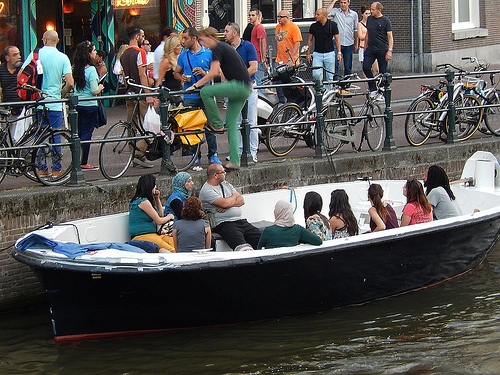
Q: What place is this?
A: It is a walkway.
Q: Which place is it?
A: It is a walkway.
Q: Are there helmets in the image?
A: No, there are no helmets.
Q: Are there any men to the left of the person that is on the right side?
A: Yes, there is a man to the left of the person.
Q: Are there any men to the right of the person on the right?
A: No, the man is to the left of the person.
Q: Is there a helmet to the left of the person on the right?
A: No, there is a man to the left of the person.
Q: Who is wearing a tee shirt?
A: The man is wearing a tee shirt.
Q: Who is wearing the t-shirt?
A: The man is wearing a tee shirt.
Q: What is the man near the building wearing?
A: The man is wearing a tee shirt.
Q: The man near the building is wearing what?
A: The man is wearing a tee shirt.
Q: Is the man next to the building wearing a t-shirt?
A: Yes, the man is wearing a t-shirt.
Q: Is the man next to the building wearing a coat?
A: No, the man is wearing a t-shirt.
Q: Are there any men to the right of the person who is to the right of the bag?
A: Yes, there is a man to the right of the person.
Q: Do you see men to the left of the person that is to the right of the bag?
A: No, the man is to the right of the person.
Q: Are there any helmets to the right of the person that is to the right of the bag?
A: No, there is a man to the right of the person.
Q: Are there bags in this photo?
A: Yes, there is a bag.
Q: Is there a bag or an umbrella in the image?
A: Yes, there is a bag.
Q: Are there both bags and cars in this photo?
A: No, there is a bag but no cars.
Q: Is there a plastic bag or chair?
A: Yes, there is a plastic bag.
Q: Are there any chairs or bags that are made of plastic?
A: Yes, the bag is made of plastic.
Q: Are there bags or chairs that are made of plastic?
A: Yes, the bag is made of plastic.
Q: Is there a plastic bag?
A: Yes, there is a bag that is made of plastic.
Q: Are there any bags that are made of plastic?
A: Yes, there is a bag that is made of plastic.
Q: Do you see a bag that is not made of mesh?
A: Yes, there is a bag that is made of plastic.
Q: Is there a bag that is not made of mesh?
A: Yes, there is a bag that is made of plastic.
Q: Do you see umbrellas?
A: No, there are no umbrellas.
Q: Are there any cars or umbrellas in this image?
A: No, there are no umbrellas or cars.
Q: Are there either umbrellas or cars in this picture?
A: No, there are no umbrellas or cars.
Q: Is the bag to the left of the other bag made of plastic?
A: Yes, the bag is made of plastic.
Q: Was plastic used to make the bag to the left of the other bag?
A: Yes, the bag is made of plastic.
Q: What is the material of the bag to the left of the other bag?
A: The bag is made of plastic.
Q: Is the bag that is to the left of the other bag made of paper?
A: No, the bag is made of plastic.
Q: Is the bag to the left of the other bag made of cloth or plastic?
A: The bag is made of plastic.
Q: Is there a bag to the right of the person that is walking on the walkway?
A: Yes, there is a bag to the right of the person.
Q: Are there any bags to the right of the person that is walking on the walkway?
A: Yes, there is a bag to the right of the person.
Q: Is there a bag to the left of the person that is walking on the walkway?
A: No, the bag is to the right of the person.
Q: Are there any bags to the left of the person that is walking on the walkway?
A: No, the bag is to the right of the person.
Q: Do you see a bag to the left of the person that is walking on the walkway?
A: No, the bag is to the right of the person.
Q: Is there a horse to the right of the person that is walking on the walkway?
A: No, there is a bag to the right of the person.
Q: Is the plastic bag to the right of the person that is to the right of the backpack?
A: Yes, the bag is to the right of the person.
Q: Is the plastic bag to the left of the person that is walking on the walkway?
A: No, the bag is to the right of the person.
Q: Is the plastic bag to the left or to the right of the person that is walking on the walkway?
A: The bag is to the right of the person.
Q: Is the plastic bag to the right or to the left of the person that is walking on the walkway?
A: The bag is to the right of the person.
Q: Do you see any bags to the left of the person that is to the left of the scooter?
A: Yes, there is a bag to the left of the person.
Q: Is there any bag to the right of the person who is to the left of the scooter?
A: No, the bag is to the left of the person.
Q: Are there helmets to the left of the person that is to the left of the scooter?
A: No, there is a bag to the left of the person.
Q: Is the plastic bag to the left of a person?
A: Yes, the bag is to the left of a person.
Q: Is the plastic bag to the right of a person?
A: No, the bag is to the left of a person.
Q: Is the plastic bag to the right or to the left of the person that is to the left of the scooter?
A: The bag is to the left of the person.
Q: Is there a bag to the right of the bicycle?
A: Yes, there is a bag to the right of the bicycle.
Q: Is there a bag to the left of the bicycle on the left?
A: No, the bag is to the right of the bicycle.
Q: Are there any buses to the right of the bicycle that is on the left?
A: No, there is a bag to the right of the bicycle.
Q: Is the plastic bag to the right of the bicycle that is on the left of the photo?
A: Yes, the bag is to the right of the bicycle.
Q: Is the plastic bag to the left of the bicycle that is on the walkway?
A: No, the bag is to the right of the bicycle.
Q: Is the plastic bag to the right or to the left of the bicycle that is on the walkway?
A: The bag is to the right of the bicycle.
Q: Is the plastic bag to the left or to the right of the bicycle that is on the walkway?
A: The bag is to the right of the bicycle.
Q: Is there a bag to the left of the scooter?
A: Yes, there is a bag to the left of the scooter.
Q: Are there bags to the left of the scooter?
A: Yes, there is a bag to the left of the scooter.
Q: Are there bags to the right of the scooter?
A: No, the bag is to the left of the scooter.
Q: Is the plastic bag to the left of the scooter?
A: Yes, the bag is to the left of the scooter.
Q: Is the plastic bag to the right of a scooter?
A: No, the bag is to the left of a scooter.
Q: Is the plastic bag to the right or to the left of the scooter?
A: The bag is to the left of the scooter.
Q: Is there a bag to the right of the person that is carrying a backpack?
A: Yes, there is a bag to the right of the person.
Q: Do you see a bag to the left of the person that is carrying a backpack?
A: No, the bag is to the right of the person.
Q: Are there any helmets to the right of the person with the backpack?
A: No, there is a bag to the right of the person.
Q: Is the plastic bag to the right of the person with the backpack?
A: Yes, the bag is to the right of the person.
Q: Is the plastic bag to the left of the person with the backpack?
A: No, the bag is to the right of the person.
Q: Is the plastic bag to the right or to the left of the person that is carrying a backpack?
A: The bag is to the right of the person.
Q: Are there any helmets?
A: No, there are no helmets.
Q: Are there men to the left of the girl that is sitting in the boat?
A: Yes, there is a man to the left of the girl.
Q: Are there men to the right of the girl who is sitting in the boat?
A: No, the man is to the left of the girl.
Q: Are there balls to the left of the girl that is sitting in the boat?
A: No, there is a man to the left of the girl.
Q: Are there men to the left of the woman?
A: Yes, there is a man to the left of the woman.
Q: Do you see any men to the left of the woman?
A: Yes, there is a man to the left of the woman.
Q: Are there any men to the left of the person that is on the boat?
A: Yes, there is a man to the left of the woman.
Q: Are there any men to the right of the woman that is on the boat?
A: No, the man is to the left of the woman.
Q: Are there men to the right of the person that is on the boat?
A: No, the man is to the left of the woman.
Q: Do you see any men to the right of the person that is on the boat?
A: No, the man is to the left of the woman.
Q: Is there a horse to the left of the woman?
A: No, there is a man to the left of the woman.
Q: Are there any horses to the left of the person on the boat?
A: No, there is a man to the left of the woman.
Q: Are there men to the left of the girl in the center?
A: Yes, there is a man to the left of the girl.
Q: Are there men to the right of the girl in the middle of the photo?
A: No, the man is to the left of the girl.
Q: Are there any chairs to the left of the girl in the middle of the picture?
A: No, there is a man to the left of the girl.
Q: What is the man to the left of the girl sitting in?
A: The man is sitting in the boat.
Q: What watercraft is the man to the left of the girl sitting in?
A: The man is sitting in the boat.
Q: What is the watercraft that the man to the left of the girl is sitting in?
A: The watercraft is a boat.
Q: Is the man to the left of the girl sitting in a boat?
A: Yes, the man is sitting in a boat.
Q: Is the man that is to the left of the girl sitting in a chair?
A: No, the man is sitting in a boat.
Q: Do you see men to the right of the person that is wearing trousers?
A: Yes, there is a man to the right of the person.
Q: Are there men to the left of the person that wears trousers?
A: No, the man is to the right of the person.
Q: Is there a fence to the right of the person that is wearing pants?
A: No, there is a man to the right of the person.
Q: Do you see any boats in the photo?
A: Yes, there is a boat.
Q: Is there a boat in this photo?
A: Yes, there is a boat.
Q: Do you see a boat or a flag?
A: Yes, there is a boat.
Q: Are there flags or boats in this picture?
A: Yes, there is a boat.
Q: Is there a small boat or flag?
A: Yes, there is a small boat.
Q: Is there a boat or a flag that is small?
A: Yes, the boat is small.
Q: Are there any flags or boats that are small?
A: Yes, the boat is small.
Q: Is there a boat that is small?
A: Yes, there is a small boat.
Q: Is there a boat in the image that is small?
A: Yes, there is a boat that is small.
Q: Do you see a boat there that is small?
A: Yes, there is a boat that is small.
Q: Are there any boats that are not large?
A: Yes, there is a small boat.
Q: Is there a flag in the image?
A: No, there are no flags.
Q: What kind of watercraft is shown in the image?
A: The watercraft is a boat.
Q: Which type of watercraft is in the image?
A: The watercraft is a boat.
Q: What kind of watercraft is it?
A: The watercraft is a boat.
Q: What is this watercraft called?
A: That is a boat.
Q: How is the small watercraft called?
A: The watercraft is a boat.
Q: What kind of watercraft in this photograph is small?
A: The watercraft is a boat.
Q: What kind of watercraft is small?
A: The watercraft is a boat.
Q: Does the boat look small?
A: Yes, the boat is small.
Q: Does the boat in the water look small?
A: Yes, the boat is small.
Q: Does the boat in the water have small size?
A: Yes, the boat is small.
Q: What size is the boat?
A: The boat is small.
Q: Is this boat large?
A: No, the boat is small.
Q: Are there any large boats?
A: No, there is a boat but it is small.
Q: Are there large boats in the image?
A: No, there is a boat but it is small.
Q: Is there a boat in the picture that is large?
A: No, there is a boat but it is small.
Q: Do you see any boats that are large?
A: No, there is a boat but it is small.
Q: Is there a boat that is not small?
A: No, there is a boat but it is small.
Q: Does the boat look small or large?
A: The boat is small.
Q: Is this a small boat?
A: Yes, this is a small boat.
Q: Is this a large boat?
A: No, this is a small boat.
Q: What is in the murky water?
A: The boat is in the water.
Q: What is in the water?
A: The boat is in the water.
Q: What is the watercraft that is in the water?
A: The watercraft is a boat.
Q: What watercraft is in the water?
A: The watercraft is a boat.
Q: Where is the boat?
A: The boat is in the water.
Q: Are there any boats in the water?
A: Yes, there is a boat in the water.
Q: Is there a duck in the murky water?
A: No, there is a boat in the water.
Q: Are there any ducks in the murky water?
A: No, there is a boat in the water.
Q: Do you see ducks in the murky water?
A: No, there is a boat in the water.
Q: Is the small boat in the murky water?
A: Yes, the boat is in the water.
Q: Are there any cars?
A: No, there are no cars.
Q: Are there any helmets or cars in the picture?
A: No, there are no cars or helmets.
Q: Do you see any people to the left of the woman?
A: Yes, there is a person to the left of the woman.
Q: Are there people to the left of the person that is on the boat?
A: Yes, there is a person to the left of the woman.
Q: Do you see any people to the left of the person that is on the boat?
A: Yes, there is a person to the left of the woman.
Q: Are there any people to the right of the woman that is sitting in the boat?
A: No, the person is to the left of the woman.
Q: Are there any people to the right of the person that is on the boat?
A: No, the person is to the left of the woman.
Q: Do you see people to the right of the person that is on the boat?
A: No, the person is to the left of the woman.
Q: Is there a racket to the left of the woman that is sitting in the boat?
A: No, there is a person to the left of the woman.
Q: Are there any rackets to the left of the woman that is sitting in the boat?
A: No, there is a person to the left of the woman.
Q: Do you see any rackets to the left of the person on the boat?
A: No, there is a person to the left of the woman.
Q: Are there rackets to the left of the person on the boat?
A: No, there is a person to the left of the woman.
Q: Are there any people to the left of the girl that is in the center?
A: Yes, there is a person to the left of the girl.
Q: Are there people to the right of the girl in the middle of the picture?
A: No, the person is to the left of the girl.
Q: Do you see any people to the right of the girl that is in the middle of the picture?
A: No, the person is to the left of the girl.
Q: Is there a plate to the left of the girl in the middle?
A: No, there is a person to the left of the girl.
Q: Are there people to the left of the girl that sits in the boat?
A: Yes, there is a person to the left of the girl.